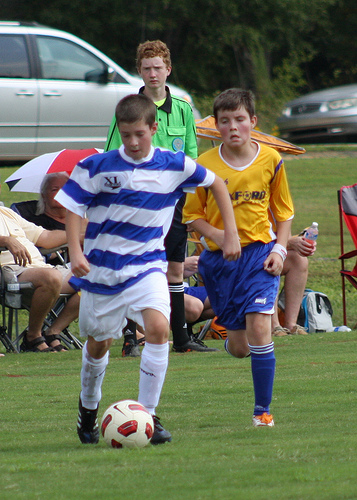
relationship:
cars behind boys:
[1, 19, 356, 166] [51, 39, 294, 446]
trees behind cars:
[1, 1, 356, 96] [1, 19, 356, 166]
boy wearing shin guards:
[54, 94, 243, 455] [81, 342, 169, 411]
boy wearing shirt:
[54, 94, 243, 455] [52, 147, 216, 293]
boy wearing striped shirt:
[54, 94, 243, 455] [52, 147, 216, 293]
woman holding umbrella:
[34, 172, 84, 352] [5, 148, 104, 193]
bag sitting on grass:
[299, 288, 334, 333] [1, 140, 356, 499]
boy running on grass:
[54, 94, 243, 455] [1, 140, 356, 499]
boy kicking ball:
[54, 94, 243, 455] [101, 398, 157, 448]